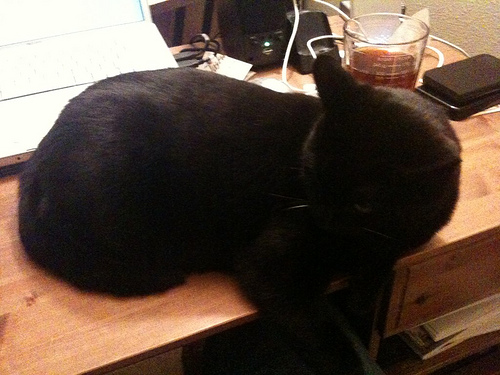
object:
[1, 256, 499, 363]
table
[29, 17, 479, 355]
photo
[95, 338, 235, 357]
edge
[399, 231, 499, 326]
drawer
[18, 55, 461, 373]
cat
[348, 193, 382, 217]
eye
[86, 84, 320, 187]
back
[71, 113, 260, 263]
body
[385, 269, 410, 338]
edge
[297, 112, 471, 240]
head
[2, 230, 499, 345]
desk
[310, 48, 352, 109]
ear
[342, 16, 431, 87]
glass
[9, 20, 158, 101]
laptop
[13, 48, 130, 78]
keyboard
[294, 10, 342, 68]
wire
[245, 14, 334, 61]
chargers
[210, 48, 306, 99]
papers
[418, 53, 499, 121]
hard drives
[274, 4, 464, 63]
cords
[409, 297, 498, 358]
papers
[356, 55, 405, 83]
liquid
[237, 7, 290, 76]
speaker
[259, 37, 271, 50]
light